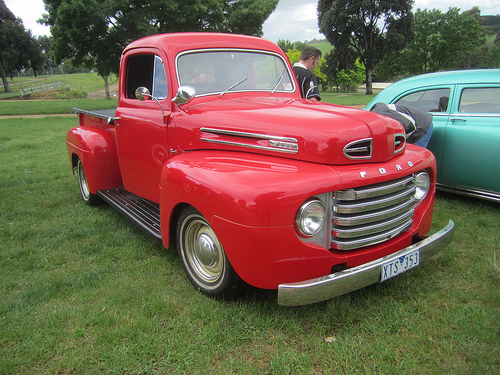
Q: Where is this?
A: This is at the field.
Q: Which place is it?
A: It is a field.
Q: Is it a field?
A: Yes, it is a field.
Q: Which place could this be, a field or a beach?
A: It is a field.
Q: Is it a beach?
A: No, it is a field.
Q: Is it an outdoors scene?
A: Yes, it is outdoors.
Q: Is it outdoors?
A: Yes, it is outdoors.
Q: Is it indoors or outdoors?
A: It is outdoors.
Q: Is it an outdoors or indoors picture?
A: It is outdoors.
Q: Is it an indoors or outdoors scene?
A: It is outdoors.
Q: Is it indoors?
A: No, it is outdoors.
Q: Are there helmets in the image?
A: No, there are no helmets.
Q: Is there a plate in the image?
A: Yes, there is a plate.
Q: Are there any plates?
A: Yes, there is a plate.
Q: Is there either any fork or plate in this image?
A: Yes, there is a plate.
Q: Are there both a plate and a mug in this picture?
A: No, there is a plate but no mugs.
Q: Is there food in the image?
A: No, there is no food.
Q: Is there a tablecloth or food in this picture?
A: No, there are no food or tablecloths.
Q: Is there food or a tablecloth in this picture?
A: No, there are no food or tablecloths.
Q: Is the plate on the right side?
A: Yes, the plate is on the right of the image.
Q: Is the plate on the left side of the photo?
A: No, the plate is on the right of the image.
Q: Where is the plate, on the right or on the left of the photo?
A: The plate is on the right of the image.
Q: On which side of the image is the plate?
A: The plate is on the right of the image.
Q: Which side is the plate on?
A: The plate is on the right of the image.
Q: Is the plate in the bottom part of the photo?
A: Yes, the plate is in the bottom of the image.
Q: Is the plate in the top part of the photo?
A: No, the plate is in the bottom of the image.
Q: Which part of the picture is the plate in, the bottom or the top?
A: The plate is in the bottom of the image.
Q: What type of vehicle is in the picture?
A: The vehicle is a car.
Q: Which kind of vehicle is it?
A: The vehicle is a car.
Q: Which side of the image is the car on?
A: The car is on the right of the image.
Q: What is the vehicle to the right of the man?
A: The vehicle is a car.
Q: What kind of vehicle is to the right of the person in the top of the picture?
A: The vehicle is a car.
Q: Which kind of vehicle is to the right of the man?
A: The vehicle is a car.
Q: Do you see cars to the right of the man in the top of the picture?
A: Yes, there is a car to the right of the man.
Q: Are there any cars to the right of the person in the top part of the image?
A: Yes, there is a car to the right of the man.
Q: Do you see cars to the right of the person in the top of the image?
A: Yes, there is a car to the right of the man.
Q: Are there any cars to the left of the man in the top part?
A: No, the car is to the right of the man.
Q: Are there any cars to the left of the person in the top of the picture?
A: No, the car is to the right of the man.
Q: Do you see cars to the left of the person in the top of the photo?
A: No, the car is to the right of the man.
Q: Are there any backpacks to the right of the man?
A: No, there is a car to the right of the man.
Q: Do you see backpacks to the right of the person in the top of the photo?
A: No, there is a car to the right of the man.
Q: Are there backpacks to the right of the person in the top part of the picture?
A: No, there is a car to the right of the man.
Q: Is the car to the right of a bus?
A: No, the car is to the right of the man.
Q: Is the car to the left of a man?
A: No, the car is to the right of a man.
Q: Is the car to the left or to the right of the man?
A: The car is to the right of the man.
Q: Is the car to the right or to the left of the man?
A: The car is to the right of the man.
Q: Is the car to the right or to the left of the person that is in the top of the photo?
A: The car is to the right of the man.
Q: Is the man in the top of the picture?
A: Yes, the man is in the top of the image.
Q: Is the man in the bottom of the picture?
A: No, the man is in the top of the image.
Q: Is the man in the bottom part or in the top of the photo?
A: The man is in the top of the image.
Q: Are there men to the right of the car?
A: No, the man is to the left of the car.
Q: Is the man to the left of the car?
A: Yes, the man is to the left of the car.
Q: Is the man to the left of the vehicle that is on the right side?
A: Yes, the man is to the left of the car.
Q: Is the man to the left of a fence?
A: No, the man is to the left of the car.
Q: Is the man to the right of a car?
A: No, the man is to the left of a car.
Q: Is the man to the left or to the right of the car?
A: The man is to the left of the car.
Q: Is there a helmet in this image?
A: No, there are no helmets.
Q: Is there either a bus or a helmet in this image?
A: No, there are no helmets or buses.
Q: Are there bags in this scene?
A: No, there are no bags.